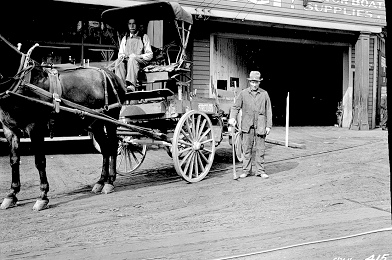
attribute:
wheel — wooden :
[168, 107, 219, 179]